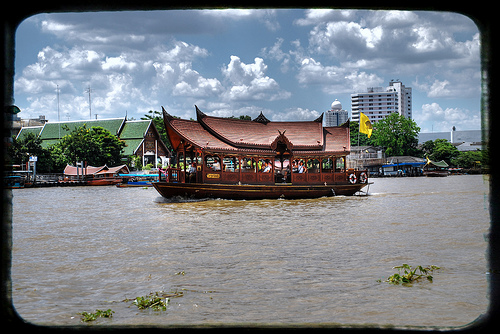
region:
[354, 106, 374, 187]
a yellow flag on the back of the boat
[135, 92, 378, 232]
an Asian style boat in the water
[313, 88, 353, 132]
a tall building in the distance with a dome top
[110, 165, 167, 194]
a smaller blue boat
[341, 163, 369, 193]
2 life rings hanging on the boat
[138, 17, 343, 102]
fluffy clouds in the sky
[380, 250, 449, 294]
plants growing out of the water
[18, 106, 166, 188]
a building with a pointy green roof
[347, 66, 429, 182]
the tallest building in the background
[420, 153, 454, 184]
a small boat with a green roof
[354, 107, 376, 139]
a small yellow flag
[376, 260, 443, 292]
leaves floating in the water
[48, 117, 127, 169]
a green tree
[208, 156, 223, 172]
a person on the boat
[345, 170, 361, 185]
a round life preserver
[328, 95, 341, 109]
the top of a building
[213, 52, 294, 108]
a white cloud in the sky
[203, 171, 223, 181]
a yellow plaque on the boat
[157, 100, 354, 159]
the roof of a boat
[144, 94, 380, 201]
a brown boat in the water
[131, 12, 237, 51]
this is the sky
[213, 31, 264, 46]
the sky is blue in color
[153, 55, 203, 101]
these are the clouds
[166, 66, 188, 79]
the clouds are white in color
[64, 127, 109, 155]
this is a tree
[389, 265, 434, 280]
this is a weed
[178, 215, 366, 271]
this is a water body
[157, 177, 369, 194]
this is a boat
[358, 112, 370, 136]
this is a flag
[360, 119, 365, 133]
the flag is yellow in color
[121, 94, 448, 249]
the pagoda is on the water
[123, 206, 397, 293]
the water is brown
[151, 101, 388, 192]
the roof is brown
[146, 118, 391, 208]
people are riding the pagoda ferry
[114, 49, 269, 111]
the clouds are gray and white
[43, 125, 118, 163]
the trees are green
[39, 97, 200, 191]
the roof is green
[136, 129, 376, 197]
the pagoda is made of wood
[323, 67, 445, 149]
the building is white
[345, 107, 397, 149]
the flag is yellow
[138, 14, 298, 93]
this is the sky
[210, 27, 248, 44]
the sky is blue in color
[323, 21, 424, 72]
these are the clouds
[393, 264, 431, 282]
this is a water weed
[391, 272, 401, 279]
the weed has green leaves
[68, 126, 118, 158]
this is a tree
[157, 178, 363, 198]
this is a boat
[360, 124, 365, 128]
the flag is yellow in color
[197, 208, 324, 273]
this is a water body